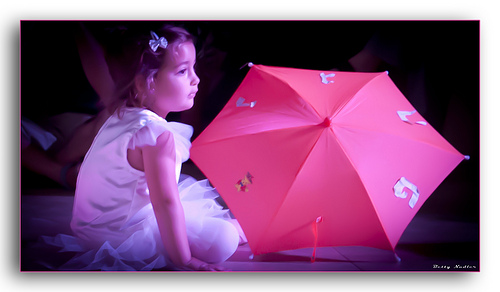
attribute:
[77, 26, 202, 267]
girl — thoughtful, little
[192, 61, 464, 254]
umbrella — pink